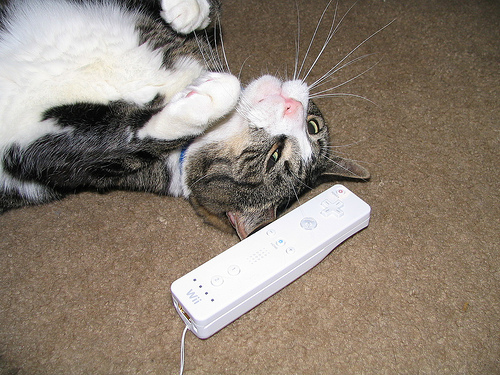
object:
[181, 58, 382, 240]
head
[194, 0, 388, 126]
whiskers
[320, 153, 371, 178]
ear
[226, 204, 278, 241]
ear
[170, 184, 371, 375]
controller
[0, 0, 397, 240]
cat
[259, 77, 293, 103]
mouth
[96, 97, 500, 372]
floor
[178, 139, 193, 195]
collar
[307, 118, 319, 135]
eye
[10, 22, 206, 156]
cat fur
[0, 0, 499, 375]
carpet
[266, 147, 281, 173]
eyes